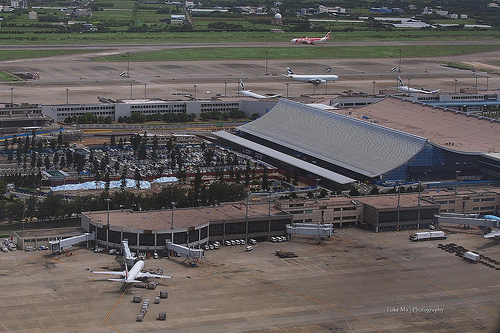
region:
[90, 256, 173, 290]
white plane parked at the terminal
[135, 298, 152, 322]
train of luggage carriers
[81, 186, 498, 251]
airport terminal airal view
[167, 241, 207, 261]
passenger loading chute to board plane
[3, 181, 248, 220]
line of trees along backside of the airport terminal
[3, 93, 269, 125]
additional passenger terminal for the airport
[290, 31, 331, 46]
red and white plane on the runway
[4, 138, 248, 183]
airport parking for travelling passengers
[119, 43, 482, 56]
green grass growing between runways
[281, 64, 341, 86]
white plane taxiing on the runway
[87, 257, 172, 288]
the plane at the airport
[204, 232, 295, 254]
the line of whtie carts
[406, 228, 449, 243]
the truck on the tar mac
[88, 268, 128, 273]
the wing of the white plane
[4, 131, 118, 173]
the trees at the airport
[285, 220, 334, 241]
the tunnel on the tar-mac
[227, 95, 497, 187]
the roof of the airport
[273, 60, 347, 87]
the white plane on the runway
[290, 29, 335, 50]
the red and white plane taking off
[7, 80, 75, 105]
the tall lights on the ground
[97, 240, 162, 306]
the airplane is parked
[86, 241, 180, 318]
the plane is white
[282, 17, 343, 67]
the plane is red and white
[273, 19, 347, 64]
the plane is getting ready to take off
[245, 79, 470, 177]
the roof is slanted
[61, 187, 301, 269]
the building is short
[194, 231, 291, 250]
the cars are parked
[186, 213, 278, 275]
the cars are white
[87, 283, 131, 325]
a yellow line on the ground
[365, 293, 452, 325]
white writing on the bottom right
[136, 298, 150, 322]
luggage car carrying luggage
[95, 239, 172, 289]
airplane at the terminal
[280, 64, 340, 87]
airplane about to take off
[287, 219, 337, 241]
terminal with no airplane at it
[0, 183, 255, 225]
trees next to the airport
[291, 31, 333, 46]
red and white airplane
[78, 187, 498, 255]
terminal building at an airport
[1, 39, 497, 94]
runway at the airport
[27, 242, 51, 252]
cars parked right next to airport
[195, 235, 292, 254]
cars parked very close to airport building